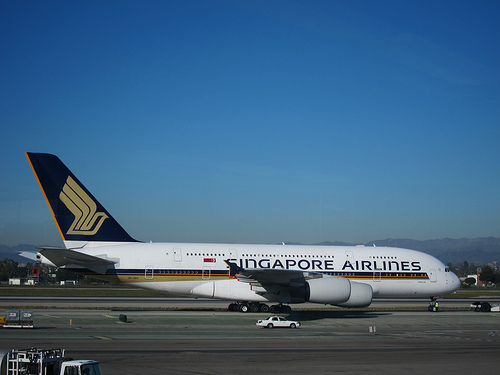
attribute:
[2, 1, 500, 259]
sky — blue, overhead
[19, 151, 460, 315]
plane — white, at airport, blue, gold, large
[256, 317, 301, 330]
car — white, small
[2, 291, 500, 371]
runway — called tarmac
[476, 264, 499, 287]
tree — green, in background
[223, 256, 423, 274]
writing — words, logo, black, the logo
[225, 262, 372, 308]
wing — patterned, black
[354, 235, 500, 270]
mountains — in the distance, tall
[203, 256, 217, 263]
sign — red, a symbol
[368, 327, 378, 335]
object — small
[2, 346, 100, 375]
truck — white, in foreground